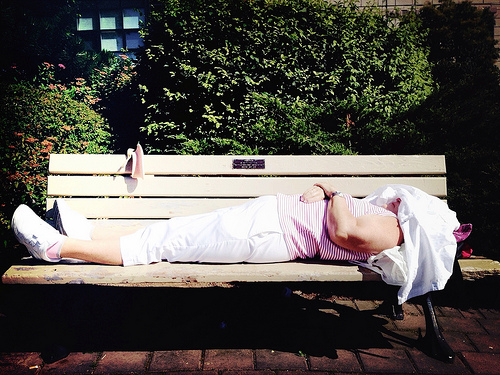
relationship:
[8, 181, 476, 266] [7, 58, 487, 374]
woman in photo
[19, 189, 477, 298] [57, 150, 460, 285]
woman laying on bench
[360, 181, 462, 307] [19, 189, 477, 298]
cloth on top of woman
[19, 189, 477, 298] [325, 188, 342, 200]
woman wearing watch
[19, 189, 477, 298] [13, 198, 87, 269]
woman wering tennis shoes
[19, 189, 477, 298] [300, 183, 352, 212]
woman has hands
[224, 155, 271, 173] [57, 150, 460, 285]
plaque on bench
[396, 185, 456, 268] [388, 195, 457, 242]
cloth on head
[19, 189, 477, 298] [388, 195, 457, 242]
woman has head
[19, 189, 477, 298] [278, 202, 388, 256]
woman wearing shirt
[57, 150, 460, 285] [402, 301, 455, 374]
bench has legs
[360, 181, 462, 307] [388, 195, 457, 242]
cloth over head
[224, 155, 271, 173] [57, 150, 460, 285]
plaque attached to bench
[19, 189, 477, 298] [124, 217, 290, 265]
woman wearing capris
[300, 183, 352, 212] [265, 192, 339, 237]
hands on top of stomach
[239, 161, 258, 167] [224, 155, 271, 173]
lettering on plaque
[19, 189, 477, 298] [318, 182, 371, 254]
woman has arms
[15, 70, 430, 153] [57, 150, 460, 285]
bushes behind bench